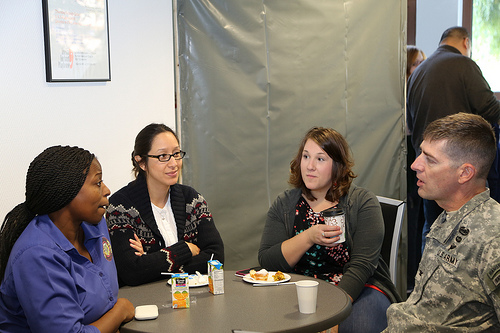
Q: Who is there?
A: People.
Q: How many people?
A: 6.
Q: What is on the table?
A: Food.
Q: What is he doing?
A: Talking.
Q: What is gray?
A: The table.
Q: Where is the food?
A: On the table.